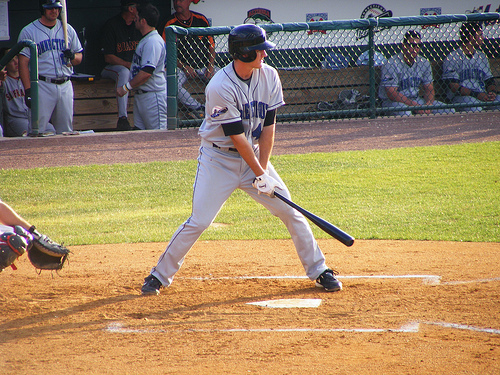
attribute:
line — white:
[202, 265, 478, 286]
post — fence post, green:
[162, 23, 179, 133]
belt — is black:
[211, 142, 237, 152]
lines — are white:
[107, 264, 499, 342]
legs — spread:
[149, 164, 329, 283]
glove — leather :
[10, 230, 72, 275]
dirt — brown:
[409, 210, 488, 298]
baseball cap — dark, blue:
[223, 24, 279, 56]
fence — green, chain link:
[158, 29, 498, 136]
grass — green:
[411, 143, 463, 210]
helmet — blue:
[226, 23, 275, 55]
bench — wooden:
[12, 62, 498, 144]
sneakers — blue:
[129, 251, 373, 328]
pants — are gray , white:
[151, 145, 333, 285]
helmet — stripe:
[248, 36, 268, 48]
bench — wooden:
[203, 45, 443, 152]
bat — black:
[250, 177, 355, 247]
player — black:
[104, 28, 397, 290]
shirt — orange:
[186, 75, 313, 154]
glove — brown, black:
[26, 231, 70, 271]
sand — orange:
[1, 239, 498, 373]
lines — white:
[106, 273, 498, 333]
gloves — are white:
[244, 167, 293, 197]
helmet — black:
[222, 18, 279, 62]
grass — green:
[0, 139, 497, 246]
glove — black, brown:
[23, 233, 72, 273]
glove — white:
[254, 169, 284, 192]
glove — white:
[250, 177, 272, 198]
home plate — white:
[231, 268, 349, 336]